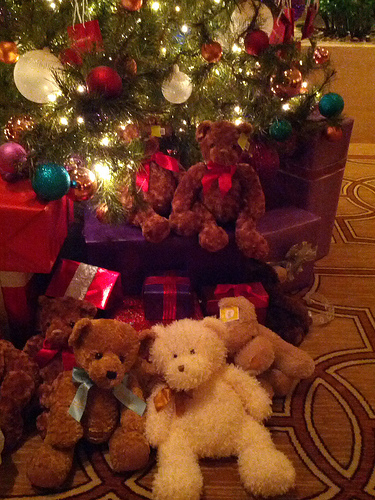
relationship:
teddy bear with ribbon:
[22, 315, 149, 490] [65, 366, 148, 425]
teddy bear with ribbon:
[12, 283, 89, 396] [30, 339, 57, 356]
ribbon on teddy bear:
[65, 366, 148, 425] [22, 318, 157, 490]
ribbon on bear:
[151, 386, 193, 418] [143, 316, 296, 498]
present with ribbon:
[141, 269, 200, 322] [143, 272, 184, 317]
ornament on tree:
[30, 159, 71, 199] [10, 8, 343, 223]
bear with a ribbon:
[171, 118, 270, 261] [198, 162, 237, 193]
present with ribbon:
[280, 111, 352, 261] [279, 158, 344, 185]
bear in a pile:
[140, 315, 300, 492] [6, 293, 316, 491]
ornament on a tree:
[10, 46, 67, 109] [10, 8, 343, 223]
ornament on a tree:
[160, 60, 194, 103] [10, 8, 343, 223]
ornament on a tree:
[198, 38, 224, 65] [10, 8, 343, 223]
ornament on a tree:
[270, 62, 302, 92] [10, 8, 343, 223]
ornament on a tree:
[312, 42, 331, 66] [10, 8, 343, 223]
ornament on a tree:
[242, 25, 269, 55] [10, 8, 343, 223]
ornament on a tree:
[317, 88, 346, 119] [10, 8, 343, 223]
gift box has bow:
[201, 272, 268, 320] [214, 274, 261, 310]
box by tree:
[44, 251, 175, 311] [21, 6, 358, 218]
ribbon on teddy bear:
[198, 159, 242, 194] [169, 118, 269, 264]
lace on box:
[159, 270, 179, 317] [140, 269, 199, 322]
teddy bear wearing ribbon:
[0, 294, 98, 455] [36, 337, 80, 368]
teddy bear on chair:
[195, 128, 270, 243] [271, 200, 309, 230]